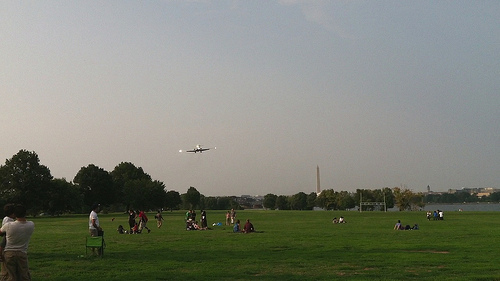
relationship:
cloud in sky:
[0, 0, 499, 200] [1, 1, 497, 197]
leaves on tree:
[36, 164, 53, 182] [1, 150, 50, 217]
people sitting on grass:
[242, 219, 261, 231] [2, 209, 499, 279]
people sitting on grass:
[231, 219, 241, 233] [2, 209, 499, 279]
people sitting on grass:
[393, 219, 416, 230] [2, 209, 499, 279]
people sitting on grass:
[186, 221, 211, 231] [2, 209, 499, 279]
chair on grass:
[81, 231, 103, 263] [2, 209, 499, 281]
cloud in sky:
[0, 0, 499, 200] [24, 31, 80, 74]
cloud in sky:
[298, 7, 339, 38] [1, 1, 497, 197]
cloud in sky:
[0, 0, 499, 200] [25, 19, 489, 154]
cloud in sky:
[0, 0, 499, 200] [0, 5, 482, 144]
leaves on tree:
[4, 149, 204, 217] [73, 164, 114, 211]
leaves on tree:
[55, 186, 77, 213] [52, 171, 82, 215]